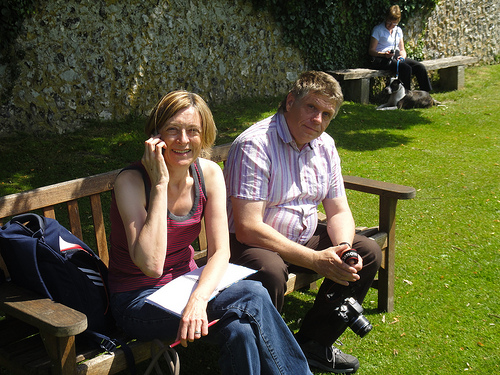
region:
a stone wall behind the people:
[11, 10, 486, 75]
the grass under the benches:
[355, 123, 492, 372]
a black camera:
[328, 274, 385, 340]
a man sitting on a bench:
[235, 87, 420, 326]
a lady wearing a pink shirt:
[134, 100, 269, 356]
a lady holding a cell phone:
[126, 82, 254, 324]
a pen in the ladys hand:
[162, 323, 227, 346]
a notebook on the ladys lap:
[148, 253, 279, 310]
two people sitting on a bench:
[97, 79, 440, 360]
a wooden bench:
[16, 142, 427, 364]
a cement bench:
[341, 57, 472, 93]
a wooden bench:
[5, 144, 409, 374]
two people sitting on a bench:
[109, 75, 411, 370]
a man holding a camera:
[246, 78, 392, 353]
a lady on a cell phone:
[127, 95, 251, 343]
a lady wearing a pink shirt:
[117, 98, 249, 336]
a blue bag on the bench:
[5, 215, 125, 310]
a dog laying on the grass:
[376, 77, 434, 110]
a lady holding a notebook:
[113, 104, 279, 364]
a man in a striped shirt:
[254, 69, 384, 339]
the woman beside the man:
[100, 86, 291, 372]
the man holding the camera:
[302, 210, 379, 350]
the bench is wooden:
[11, 145, 407, 350]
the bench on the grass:
[15, 100, 470, 370]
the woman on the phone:
[125, 90, 240, 185]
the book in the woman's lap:
[125, 245, 260, 325]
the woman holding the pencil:
[161, 295, 221, 350]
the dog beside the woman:
[357, 71, 473, 118]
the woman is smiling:
[145, 98, 220, 180]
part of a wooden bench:
[0, 171, 157, 373]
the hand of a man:
[310, 240, 358, 290]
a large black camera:
[323, 293, 375, 340]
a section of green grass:
[349, 108, 499, 205]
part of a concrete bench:
[416, 48, 473, 89]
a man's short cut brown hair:
[280, 68, 343, 121]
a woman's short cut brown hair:
[146, 88, 220, 160]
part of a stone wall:
[2, 0, 309, 134]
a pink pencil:
[166, 310, 223, 355]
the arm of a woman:
[117, 168, 170, 282]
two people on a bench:
[88, 66, 421, 373]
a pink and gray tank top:
[86, 146, 222, 323]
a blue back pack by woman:
[8, 194, 140, 325]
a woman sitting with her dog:
[366, 2, 461, 126]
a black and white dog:
[368, 65, 463, 118]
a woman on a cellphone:
[111, 79, 218, 161]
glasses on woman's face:
[384, 14, 404, 31]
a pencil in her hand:
[144, 305, 258, 347]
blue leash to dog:
[390, 44, 405, 91]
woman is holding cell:
[131, 141, 193, 173]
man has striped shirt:
[190, 90, 407, 305]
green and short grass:
[415, 145, 492, 235]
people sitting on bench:
[1, 102, 413, 359]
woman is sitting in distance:
[358, 2, 476, 121]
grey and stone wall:
[11, 1, 266, 114]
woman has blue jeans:
[169, 282, 319, 372]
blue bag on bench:
[8, 155, 85, 342]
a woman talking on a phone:
[94, 73, 296, 374]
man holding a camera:
[228, 52, 415, 345]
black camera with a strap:
[307, 230, 412, 360]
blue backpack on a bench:
[4, 188, 131, 362]